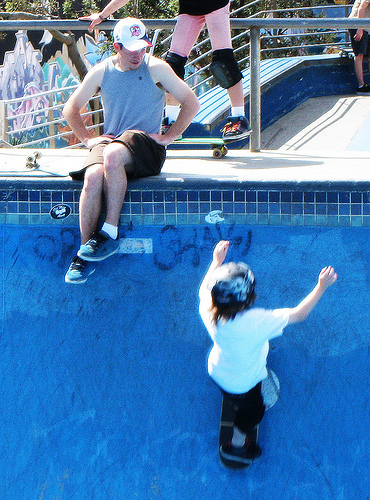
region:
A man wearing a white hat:
[40, 11, 201, 299]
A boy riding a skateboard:
[166, 224, 337, 471]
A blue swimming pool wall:
[7, 296, 155, 484]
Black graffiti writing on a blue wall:
[148, 212, 270, 264]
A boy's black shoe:
[213, 429, 259, 453]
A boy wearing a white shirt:
[171, 224, 346, 476]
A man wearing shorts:
[37, 5, 211, 295]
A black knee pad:
[200, 34, 248, 90]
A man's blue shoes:
[60, 219, 123, 286]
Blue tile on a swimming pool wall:
[235, 186, 353, 224]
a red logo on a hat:
[128, 20, 141, 36]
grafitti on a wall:
[149, 217, 257, 265]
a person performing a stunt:
[198, 241, 311, 475]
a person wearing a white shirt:
[199, 240, 297, 471]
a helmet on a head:
[215, 262, 257, 302]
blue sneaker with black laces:
[66, 234, 114, 288]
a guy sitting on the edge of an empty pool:
[53, 18, 162, 283]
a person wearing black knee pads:
[111, 0, 238, 153]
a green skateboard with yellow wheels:
[166, 141, 238, 155]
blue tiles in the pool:
[133, 192, 360, 225]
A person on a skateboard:
[196, 235, 335, 458]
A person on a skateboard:
[75, 0, 247, 140]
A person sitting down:
[57, 13, 197, 283]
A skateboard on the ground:
[0, 148, 67, 177]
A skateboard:
[214, 390, 260, 471]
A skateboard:
[166, 134, 251, 160]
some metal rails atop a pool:
[1, 18, 368, 152]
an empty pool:
[0, 179, 364, 497]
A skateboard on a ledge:
[334, 45, 353, 59]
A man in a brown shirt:
[347, 0, 368, 96]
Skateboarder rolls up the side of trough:
[196, 237, 340, 472]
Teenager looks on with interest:
[64, 14, 202, 285]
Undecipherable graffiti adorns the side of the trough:
[31, 219, 257, 276]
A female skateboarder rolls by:
[78, 1, 250, 156]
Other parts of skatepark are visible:
[0, 0, 369, 149]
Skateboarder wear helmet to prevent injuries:
[208, 259, 257, 324]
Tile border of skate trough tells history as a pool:
[0, 180, 368, 228]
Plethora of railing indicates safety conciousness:
[0, 1, 368, 149]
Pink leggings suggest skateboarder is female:
[163, 1, 239, 59]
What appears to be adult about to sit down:
[342, 0, 368, 95]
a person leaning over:
[343, 1, 368, 96]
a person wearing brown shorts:
[63, 24, 164, 279]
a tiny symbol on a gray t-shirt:
[139, 76, 145, 82]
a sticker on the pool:
[45, 202, 73, 219]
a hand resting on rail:
[83, 6, 106, 30]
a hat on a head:
[108, 17, 157, 55]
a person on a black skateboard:
[199, 245, 278, 481]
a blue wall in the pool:
[1, 227, 349, 498]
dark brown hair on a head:
[212, 306, 238, 316]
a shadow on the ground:
[237, 148, 322, 172]